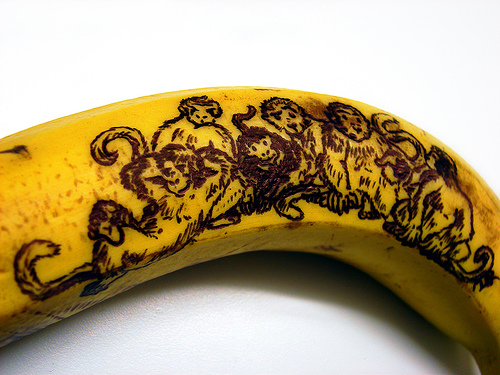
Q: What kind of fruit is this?
A: Banana.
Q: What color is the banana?
A: Yellow.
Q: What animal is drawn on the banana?
A: Monkeys.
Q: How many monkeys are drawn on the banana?
A: Six.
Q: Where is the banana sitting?
A: White surface.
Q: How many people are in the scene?
A: None.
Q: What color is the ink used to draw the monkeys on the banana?
A: Black.